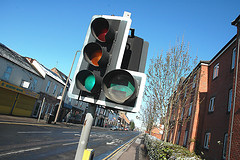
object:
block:
[0, 114, 146, 160]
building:
[0, 78, 41, 119]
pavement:
[0, 114, 107, 128]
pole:
[72, 103, 96, 160]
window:
[222, 133, 228, 159]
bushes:
[143, 132, 202, 159]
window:
[208, 98, 213, 112]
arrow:
[104, 140, 116, 146]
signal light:
[100, 68, 139, 104]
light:
[83, 73, 95, 92]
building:
[160, 59, 209, 153]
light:
[90, 19, 110, 43]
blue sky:
[0, 0, 239, 131]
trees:
[152, 32, 207, 143]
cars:
[109, 126, 117, 131]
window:
[215, 65, 219, 78]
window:
[230, 46, 236, 70]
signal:
[80, 41, 104, 67]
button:
[84, 147, 94, 151]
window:
[203, 132, 207, 149]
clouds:
[0, 0, 240, 132]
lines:
[16, 130, 52, 134]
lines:
[60, 131, 81, 134]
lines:
[105, 135, 137, 160]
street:
[0, 118, 144, 160]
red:
[98, 30, 106, 38]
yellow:
[92, 51, 99, 61]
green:
[83, 74, 93, 87]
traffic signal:
[66, 10, 147, 113]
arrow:
[107, 80, 134, 97]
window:
[212, 66, 216, 80]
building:
[193, 14, 240, 159]